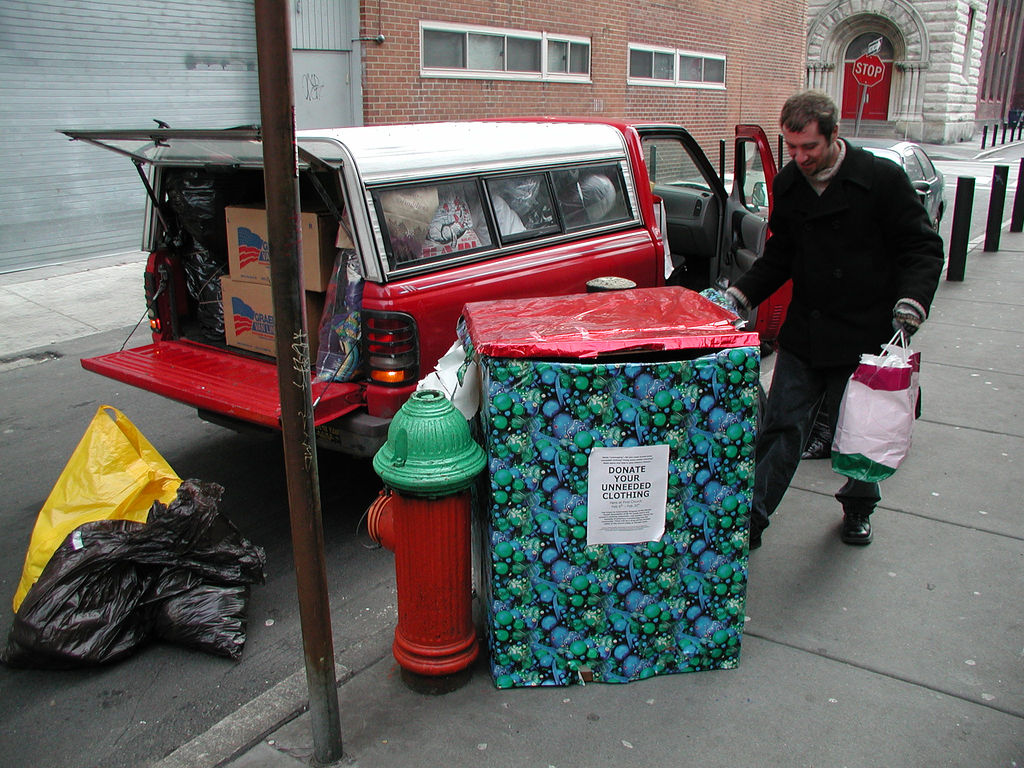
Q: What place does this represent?
A: It represents the street.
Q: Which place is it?
A: It is a street.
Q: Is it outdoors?
A: Yes, it is outdoors.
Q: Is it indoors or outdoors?
A: It is outdoors.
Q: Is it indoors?
A: No, it is outdoors.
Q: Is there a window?
A: Yes, there are windows.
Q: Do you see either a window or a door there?
A: Yes, there are windows.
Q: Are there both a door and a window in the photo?
A: Yes, there are both a window and a door.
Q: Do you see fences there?
A: No, there are no fences.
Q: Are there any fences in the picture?
A: No, there are no fences.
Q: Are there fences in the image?
A: No, there are no fences.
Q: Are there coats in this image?
A: Yes, there is a coat.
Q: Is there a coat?
A: Yes, there is a coat.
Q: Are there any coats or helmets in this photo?
A: Yes, there is a coat.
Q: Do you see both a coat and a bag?
A: Yes, there are both a coat and a bag.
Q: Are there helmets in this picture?
A: No, there are no helmets.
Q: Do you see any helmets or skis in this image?
A: No, there are no helmets or skis.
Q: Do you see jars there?
A: No, there are no jars.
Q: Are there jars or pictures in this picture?
A: No, there are no jars or pictures.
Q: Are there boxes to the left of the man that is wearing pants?
A: Yes, there is a box to the left of the man.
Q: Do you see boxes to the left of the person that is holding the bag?
A: Yes, there is a box to the left of the man.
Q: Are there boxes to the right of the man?
A: No, the box is to the left of the man.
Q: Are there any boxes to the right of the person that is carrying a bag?
A: No, the box is to the left of the man.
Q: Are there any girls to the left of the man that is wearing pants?
A: No, there is a box to the left of the man.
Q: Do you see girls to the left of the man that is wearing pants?
A: No, there is a box to the left of the man.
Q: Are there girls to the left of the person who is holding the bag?
A: No, there is a box to the left of the man.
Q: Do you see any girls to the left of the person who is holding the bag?
A: No, there is a box to the left of the man.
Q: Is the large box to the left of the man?
A: Yes, the box is to the left of the man.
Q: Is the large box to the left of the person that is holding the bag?
A: Yes, the box is to the left of the man.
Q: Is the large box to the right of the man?
A: No, the box is to the left of the man.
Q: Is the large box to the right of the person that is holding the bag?
A: No, the box is to the left of the man.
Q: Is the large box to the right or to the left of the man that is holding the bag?
A: The box is to the left of the man.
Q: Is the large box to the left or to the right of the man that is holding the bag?
A: The box is to the left of the man.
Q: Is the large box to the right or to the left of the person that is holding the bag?
A: The box is to the left of the man.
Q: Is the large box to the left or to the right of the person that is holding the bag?
A: The box is to the left of the man.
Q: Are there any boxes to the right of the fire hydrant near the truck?
A: Yes, there is a box to the right of the fire hydrant.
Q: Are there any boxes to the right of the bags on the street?
A: Yes, there is a box to the right of the bags.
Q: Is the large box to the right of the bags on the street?
A: Yes, the box is to the right of the bags.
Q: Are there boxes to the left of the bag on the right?
A: Yes, there is a box to the left of the bag.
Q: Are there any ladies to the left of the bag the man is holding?
A: No, there is a box to the left of the bag.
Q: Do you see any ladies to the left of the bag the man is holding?
A: No, there is a box to the left of the bag.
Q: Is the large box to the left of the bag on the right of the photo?
A: Yes, the box is to the left of the bag.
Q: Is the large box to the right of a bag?
A: No, the box is to the left of a bag.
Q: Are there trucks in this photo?
A: Yes, there is a truck.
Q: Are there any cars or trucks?
A: Yes, there is a truck.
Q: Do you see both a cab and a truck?
A: No, there is a truck but no taxis.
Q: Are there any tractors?
A: No, there are no tractors.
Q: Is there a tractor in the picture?
A: No, there are no tractors.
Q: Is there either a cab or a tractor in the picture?
A: No, there are no tractors or taxis.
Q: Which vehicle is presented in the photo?
A: The vehicle is a truck.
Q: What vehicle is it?
A: The vehicle is a truck.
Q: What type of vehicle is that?
A: This is a truck.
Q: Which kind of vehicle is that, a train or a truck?
A: This is a truck.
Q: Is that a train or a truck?
A: That is a truck.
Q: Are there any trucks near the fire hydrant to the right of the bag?
A: Yes, there is a truck near the fire hydrant.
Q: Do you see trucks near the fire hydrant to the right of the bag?
A: Yes, there is a truck near the fire hydrant.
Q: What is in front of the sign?
A: The truck is in front of the sign.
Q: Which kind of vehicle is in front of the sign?
A: The vehicle is a truck.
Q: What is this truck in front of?
A: The truck is in front of the sign.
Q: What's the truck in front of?
A: The truck is in front of the sign.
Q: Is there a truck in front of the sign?
A: Yes, there is a truck in front of the sign.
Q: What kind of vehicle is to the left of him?
A: The vehicle is a truck.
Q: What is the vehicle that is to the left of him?
A: The vehicle is a truck.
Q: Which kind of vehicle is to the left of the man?
A: The vehicle is a truck.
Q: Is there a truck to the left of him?
A: Yes, there is a truck to the left of the man.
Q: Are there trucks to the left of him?
A: Yes, there is a truck to the left of the man.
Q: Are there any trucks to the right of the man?
A: No, the truck is to the left of the man.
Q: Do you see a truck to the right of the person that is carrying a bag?
A: No, the truck is to the left of the man.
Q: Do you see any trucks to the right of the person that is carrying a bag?
A: No, the truck is to the left of the man.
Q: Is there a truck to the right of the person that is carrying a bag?
A: No, the truck is to the left of the man.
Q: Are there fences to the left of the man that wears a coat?
A: No, there is a truck to the left of the man.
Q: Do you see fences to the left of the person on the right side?
A: No, there is a truck to the left of the man.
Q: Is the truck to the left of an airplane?
A: No, the truck is to the left of the man.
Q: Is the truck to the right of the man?
A: No, the truck is to the left of the man.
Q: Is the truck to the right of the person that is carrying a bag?
A: No, the truck is to the left of the man.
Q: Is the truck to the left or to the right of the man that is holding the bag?
A: The truck is to the left of the man.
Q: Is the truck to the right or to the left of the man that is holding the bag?
A: The truck is to the left of the man.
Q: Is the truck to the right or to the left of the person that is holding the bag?
A: The truck is to the left of the man.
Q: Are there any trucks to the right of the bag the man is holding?
A: No, the truck is to the left of the bag.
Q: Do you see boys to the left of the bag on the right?
A: No, there is a truck to the left of the bag.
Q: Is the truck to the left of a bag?
A: Yes, the truck is to the left of a bag.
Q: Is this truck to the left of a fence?
A: No, the truck is to the left of a bag.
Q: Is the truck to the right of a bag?
A: No, the truck is to the left of a bag.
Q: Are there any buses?
A: No, there are no buses.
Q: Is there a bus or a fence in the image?
A: No, there are no buses or fences.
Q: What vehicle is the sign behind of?
A: The sign is behind the truck.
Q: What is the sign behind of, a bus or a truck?
A: The sign is behind a truck.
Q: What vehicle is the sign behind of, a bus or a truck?
A: The sign is behind a truck.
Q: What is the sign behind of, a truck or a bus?
A: The sign is behind a truck.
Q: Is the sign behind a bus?
A: No, the sign is behind the truck.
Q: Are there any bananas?
A: No, there are no bananas.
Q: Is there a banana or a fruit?
A: No, there are no bananas or fruits.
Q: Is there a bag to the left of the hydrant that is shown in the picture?
A: Yes, there are bags to the left of the hydrant.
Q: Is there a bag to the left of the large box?
A: Yes, there are bags to the left of the box.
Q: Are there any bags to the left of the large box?
A: Yes, there are bags to the left of the box.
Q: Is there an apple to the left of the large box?
A: No, there are bags to the left of the box.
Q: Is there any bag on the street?
A: Yes, there are bags on the street.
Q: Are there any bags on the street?
A: Yes, there are bags on the street.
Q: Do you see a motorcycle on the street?
A: No, there are bags on the street.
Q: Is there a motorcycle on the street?
A: No, there are bags on the street.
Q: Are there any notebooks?
A: No, there are no notebooks.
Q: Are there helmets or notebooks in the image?
A: No, there are no notebooks or helmets.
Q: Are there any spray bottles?
A: No, there are no spray bottles.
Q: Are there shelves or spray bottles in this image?
A: No, there are no spray bottles or shelves.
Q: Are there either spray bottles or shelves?
A: No, there are no spray bottles or shelves.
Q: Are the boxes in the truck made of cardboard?
A: Yes, the boxes are made of cardboard.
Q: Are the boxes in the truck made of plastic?
A: No, the boxes are made of cardboard.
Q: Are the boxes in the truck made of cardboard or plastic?
A: The boxes are made of cardboard.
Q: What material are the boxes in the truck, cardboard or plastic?
A: The boxes are made of cardboard.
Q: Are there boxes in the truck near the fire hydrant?
A: Yes, there are boxes in the truck.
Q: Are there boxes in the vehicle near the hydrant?
A: Yes, there are boxes in the truck.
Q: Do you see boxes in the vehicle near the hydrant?
A: Yes, there are boxes in the truck.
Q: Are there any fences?
A: No, there are no fences.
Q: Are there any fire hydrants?
A: Yes, there is a fire hydrant.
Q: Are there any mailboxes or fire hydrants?
A: Yes, there is a fire hydrant.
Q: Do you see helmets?
A: No, there are no helmets.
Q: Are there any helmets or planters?
A: No, there are no helmets or planters.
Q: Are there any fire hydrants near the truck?
A: Yes, there is a fire hydrant near the truck.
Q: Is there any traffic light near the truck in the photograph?
A: No, there is a fire hydrant near the truck.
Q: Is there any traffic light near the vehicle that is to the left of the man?
A: No, there is a fire hydrant near the truck.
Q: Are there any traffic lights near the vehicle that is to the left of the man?
A: No, there is a fire hydrant near the truck.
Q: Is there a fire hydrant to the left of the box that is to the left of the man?
A: Yes, there is a fire hydrant to the left of the box.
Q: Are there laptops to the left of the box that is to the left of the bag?
A: No, there is a fire hydrant to the left of the box.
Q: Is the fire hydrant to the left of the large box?
A: Yes, the fire hydrant is to the left of the box.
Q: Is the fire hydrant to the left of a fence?
A: No, the fire hydrant is to the left of the box.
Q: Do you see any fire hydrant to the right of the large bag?
A: Yes, there is a fire hydrant to the right of the bag.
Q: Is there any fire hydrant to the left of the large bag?
A: No, the fire hydrant is to the right of the bag.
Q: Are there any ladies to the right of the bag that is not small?
A: No, there is a fire hydrant to the right of the bag.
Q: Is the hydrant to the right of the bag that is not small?
A: Yes, the hydrant is to the right of the bag.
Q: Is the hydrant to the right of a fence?
A: No, the hydrant is to the right of the bag.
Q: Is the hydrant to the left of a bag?
A: No, the hydrant is to the right of a bag.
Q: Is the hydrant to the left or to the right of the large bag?
A: The hydrant is to the right of the bag.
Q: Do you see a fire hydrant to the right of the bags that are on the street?
A: Yes, there is a fire hydrant to the right of the bags.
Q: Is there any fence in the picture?
A: No, there are no fences.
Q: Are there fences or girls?
A: No, there are no fences or girls.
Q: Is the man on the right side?
A: Yes, the man is on the right of the image.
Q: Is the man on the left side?
A: No, the man is on the right of the image.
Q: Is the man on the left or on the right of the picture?
A: The man is on the right of the image.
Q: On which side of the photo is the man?
A: The man is on the right of the image.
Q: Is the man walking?
A: Yes, the man is walking.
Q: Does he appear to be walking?
A: Yes, the man is walking.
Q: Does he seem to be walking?
A: Yes, the man is walking.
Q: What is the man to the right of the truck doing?
A: The man is walking.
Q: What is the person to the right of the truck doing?
A: The man is walking.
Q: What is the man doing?
A: The man is walking.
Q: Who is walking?
A: The man is walking.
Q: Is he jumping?
A: No, the man is walking.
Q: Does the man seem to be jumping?
A: No, the man is walking.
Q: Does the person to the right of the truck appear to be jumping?
A: No, the man is walking.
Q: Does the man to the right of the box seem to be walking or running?
A: The man is walking.